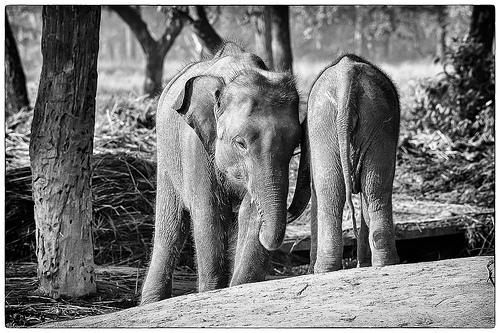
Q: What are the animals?
A: Elephants.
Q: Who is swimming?
A: No one.